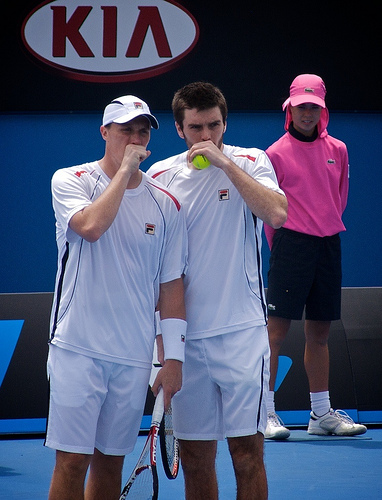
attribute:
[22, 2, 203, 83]
logo — car company, red, white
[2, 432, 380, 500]
ground — blue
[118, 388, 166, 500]
tennis racket — red, black, white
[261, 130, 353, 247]
shirt — pink, black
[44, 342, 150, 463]
shorts — white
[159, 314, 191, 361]
wristband — white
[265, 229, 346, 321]
shorts — black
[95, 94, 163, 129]
hat — white, black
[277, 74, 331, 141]
hat — pink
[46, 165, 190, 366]
shirt — white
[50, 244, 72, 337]
stripe — black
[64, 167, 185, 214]
stripes — red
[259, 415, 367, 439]
shoes — white